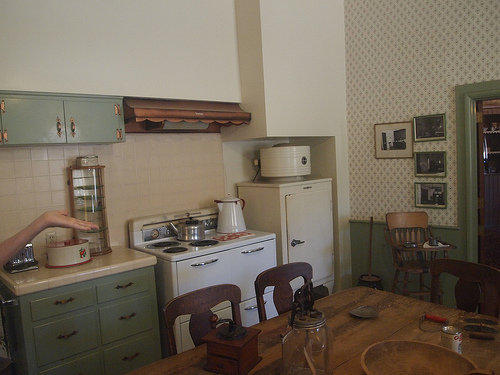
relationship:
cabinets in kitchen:
[6, 91, 135, 154] [2, 2, 492, 372]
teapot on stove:
[173, 213, 209, 247] [135, 207, 278, 336]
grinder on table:
[197, 313, 271, 371] [142, 274, 498, 372]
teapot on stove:
[167, 214, 206, 241] [157, 202, 284, 360]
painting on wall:
[368, 116, 418, 166] [350, 69, 415, 210]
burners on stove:
[146, 234, 196, 259] [132, 207, 282, 327]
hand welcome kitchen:
[4, 204, 109, 269] [2, 2, 492, 372]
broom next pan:
[352, 213, 381, 282] [359, 274, 386, 292]